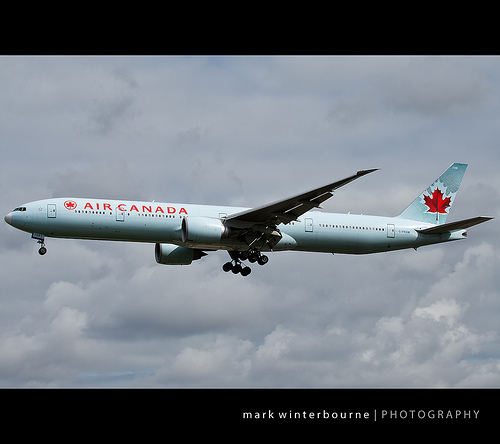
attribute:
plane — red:
[7, 162, 493, 273]